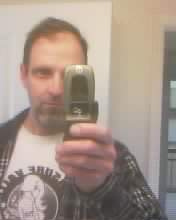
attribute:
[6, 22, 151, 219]
man — taking picture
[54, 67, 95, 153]
cell — camera, flip phone, old, grey, flipped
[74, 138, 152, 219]
shirt — plaid, white, long-sleeve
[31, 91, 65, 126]
beard — small, black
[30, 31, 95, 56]
hairline — receding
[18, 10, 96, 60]
hair — short, brown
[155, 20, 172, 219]
room — adjoining